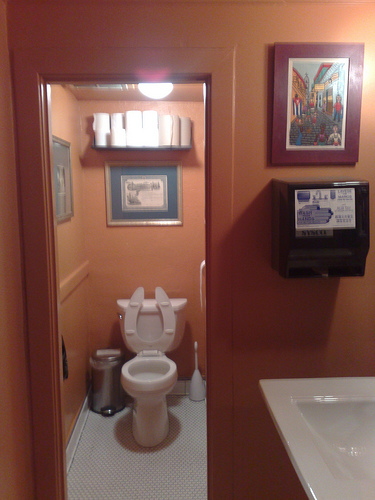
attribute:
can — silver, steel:
[85, 351, 125, 418]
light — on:
[135, 81, 178, 103]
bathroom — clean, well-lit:
[55, 82, 211, 499]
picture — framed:
[271, 46, 363, 169]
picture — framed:
[106, 162, 180, 227]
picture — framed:
[44, 141, 76, 220]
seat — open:
[120, 286, 179, 353]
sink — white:
[263, 380, 373, 500]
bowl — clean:
[120, 360, 178, 385]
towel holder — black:
[269, 176, 368, 277]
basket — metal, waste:
[86, 346, 128, 415]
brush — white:
[85, 114, 194, 173]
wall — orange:
[78, 99, 210, 392]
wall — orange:
[47, 82, 101, 466]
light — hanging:
[137, 81, 176, 100]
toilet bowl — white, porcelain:
[108, 289, 194, 457]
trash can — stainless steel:
[81, 308, 152, 430]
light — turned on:
[137, 84, 173, 100]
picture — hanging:
[49, 137, 80, 230]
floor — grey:
[87, 445, 200, 495]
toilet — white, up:
[115, 285, 189, 446]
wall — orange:
[212, 5, 371, 495]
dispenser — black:
[266, 177, 372, 279]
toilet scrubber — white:
[185, 340, 204, 404]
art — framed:
[256, 33, 369, 144]